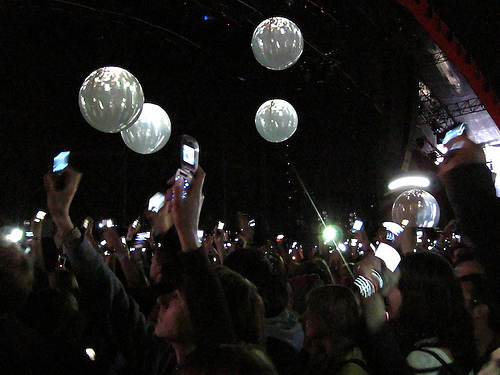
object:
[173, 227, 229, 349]
arm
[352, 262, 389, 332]
arm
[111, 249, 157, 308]
arm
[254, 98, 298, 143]
lamp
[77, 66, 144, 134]
lamp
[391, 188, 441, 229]
lamp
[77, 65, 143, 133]
ball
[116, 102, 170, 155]
ball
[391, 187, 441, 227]
ball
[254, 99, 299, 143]
ball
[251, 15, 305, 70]
ball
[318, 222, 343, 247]
light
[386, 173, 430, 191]
light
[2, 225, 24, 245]
light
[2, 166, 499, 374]
people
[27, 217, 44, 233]
hand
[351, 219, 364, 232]
light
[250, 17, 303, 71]
lamp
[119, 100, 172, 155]
lamp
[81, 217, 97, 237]
hand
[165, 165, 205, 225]
hand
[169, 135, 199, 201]
cellular phone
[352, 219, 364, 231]
cellular phone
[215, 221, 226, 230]
cellular phone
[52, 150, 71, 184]
cellular phone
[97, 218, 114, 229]
cellphone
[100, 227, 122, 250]
hand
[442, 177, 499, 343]
arm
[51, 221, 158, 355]
arm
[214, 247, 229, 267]
arms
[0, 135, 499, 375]
crowd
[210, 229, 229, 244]
hand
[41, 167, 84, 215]
hand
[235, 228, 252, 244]
hand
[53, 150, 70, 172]
screen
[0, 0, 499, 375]
warehouse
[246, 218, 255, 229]
cellphones